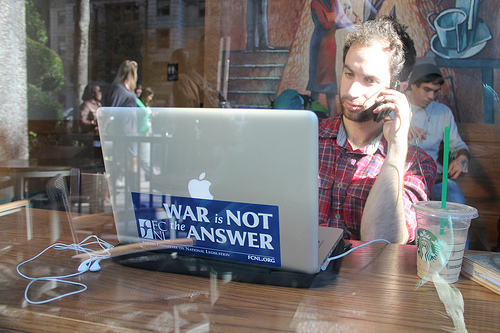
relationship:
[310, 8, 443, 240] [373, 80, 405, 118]
man has cell phone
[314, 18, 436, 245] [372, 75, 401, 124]
man holds phone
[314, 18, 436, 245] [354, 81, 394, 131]
man uses cell phone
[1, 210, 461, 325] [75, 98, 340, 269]
table beneath computer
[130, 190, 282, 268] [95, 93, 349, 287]
sticker on laptop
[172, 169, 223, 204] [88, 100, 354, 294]
logo on laptop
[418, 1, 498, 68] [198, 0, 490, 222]
cup painting on wall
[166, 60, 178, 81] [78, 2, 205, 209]
sign on wall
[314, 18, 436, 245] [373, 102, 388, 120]
man talking on cellphone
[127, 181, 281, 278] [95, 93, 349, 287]
sticker on laptop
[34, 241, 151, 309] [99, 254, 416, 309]
headphones on desk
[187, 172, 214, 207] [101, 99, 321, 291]
logo on computer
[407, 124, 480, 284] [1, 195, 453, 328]
cup on table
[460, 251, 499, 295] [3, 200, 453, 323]
book on top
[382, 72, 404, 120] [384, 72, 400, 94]
phone up to ear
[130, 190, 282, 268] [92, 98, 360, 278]
sticker on laptop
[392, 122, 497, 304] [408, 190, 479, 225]
cup with lid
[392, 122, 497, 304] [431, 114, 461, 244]
cup with straw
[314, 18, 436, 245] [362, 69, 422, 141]
man on telephone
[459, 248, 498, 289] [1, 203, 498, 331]
book resting on table